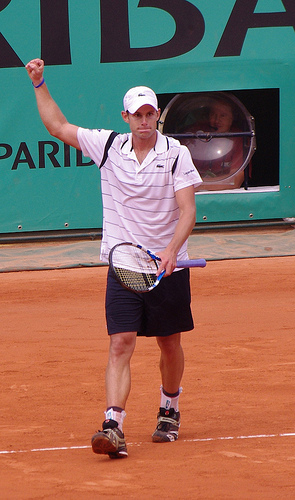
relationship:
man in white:
[42, 35, 261, 472] [60, 111, 214, 304]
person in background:
[176, 71, 250, 191] [1, 63, 261, 286]